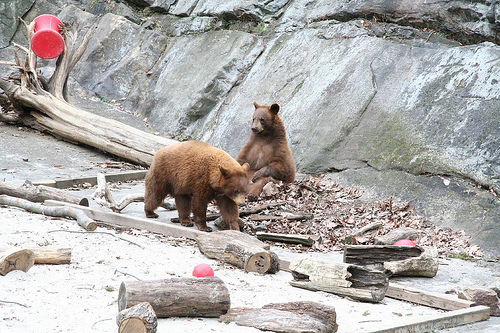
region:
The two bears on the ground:
[131, 94, 324, 240]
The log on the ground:
[114, 278, 237, 319]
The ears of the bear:
[213, 158, 257, 175]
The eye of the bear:
[255, 113, 270, 124]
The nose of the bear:
[246, 122, 262, 133]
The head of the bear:
[243, 96, 281, 136]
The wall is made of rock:
[316, 15, 495, 212]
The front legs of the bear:
[191, 196, 242, 233]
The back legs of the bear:
[141, 178, 195, 228]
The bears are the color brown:
[142, 96, 295, 233]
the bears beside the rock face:
[141, 86, 307, 223]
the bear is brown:
[233, 96, 313, 192]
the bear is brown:
[130, 131, 255, 226]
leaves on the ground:
[275, 176, 355, 227]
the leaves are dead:
[260, 177, 400, 242]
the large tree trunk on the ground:
[19, 68, 179, 180]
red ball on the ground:
[173, 257, 226, 278]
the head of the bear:
[212, 156, 265, 209]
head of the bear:
[244, 99, 286, 137]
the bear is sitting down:
[221, 96, 316, 206]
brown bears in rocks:
[155, 94, 295, 219]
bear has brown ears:
[243, 101, 282, 128]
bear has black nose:
[228, 166, 246, 210]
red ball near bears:
[184, 256, 226, 284]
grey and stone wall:
[188, 14, 497, 153]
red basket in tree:
[21, 14, 101, 69]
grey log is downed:
[15, 84, 197, 163]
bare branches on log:
[18, 34, 92, 111]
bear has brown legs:
[116, 151, 218, 224]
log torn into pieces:
[316, 224, 427, 312]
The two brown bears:
[142, 102, 294, 231]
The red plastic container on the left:
[31, 12, 66, 60]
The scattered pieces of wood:
[0, 18, 499, 331]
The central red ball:
[189, 263, 215, 278]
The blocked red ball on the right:
[392, 235, 417, 249]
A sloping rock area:
[0, 0, 499, 262]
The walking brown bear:
[147, 133, 250, 236]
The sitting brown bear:
[234, 104, 296, 196]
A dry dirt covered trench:
[0, 0, 498, 332]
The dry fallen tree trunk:
[1, 17, 193, 169]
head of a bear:
[235, 92, 286, 142]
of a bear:
[220, 157, 255, 210]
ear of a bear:
[210, 159, 230, 174]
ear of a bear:
[235, 157, 257, 169]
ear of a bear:
[248, 90, 262, 115]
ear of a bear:
[268, 101, 284, 110]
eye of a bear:
[257, 114, 274, 128]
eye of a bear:
[230, 187, 245, 196]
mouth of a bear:
[228, 197, 245, 209]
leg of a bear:
[223, 205, 253, 227]